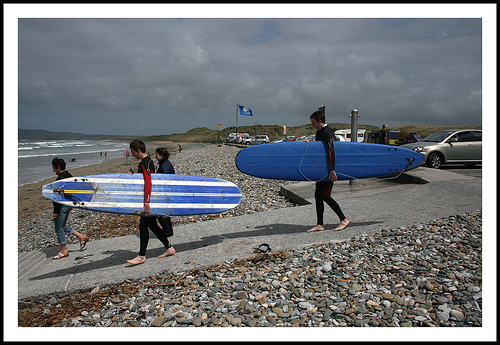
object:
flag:
[238, 104, 253, 117]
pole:
[235, 104, 239, 145]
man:
[306, 109, 350, 233]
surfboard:
[235, 139, 425, 181]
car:
[397, 129, 480, 169]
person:
[50, 157, 88, 260]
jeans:
[53, 205, 76, 244]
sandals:
[52, 253, 69, 260]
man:
[125, 139, 177, 265]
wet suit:
[137, 155, 173, 258]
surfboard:
[39, 172, 246, 217]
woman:
[156, 146, 177, 238]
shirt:
[155, 158, 175, 174]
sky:
[18, 19, 481, 136]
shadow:
[220, 219, 383, 239]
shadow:
[30, 234, 227, 282]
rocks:
[19, 210, 484, 326]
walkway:
[18, 176, 481, 301]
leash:
[297, 140, 416, 184]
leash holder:
[404, 158, 415, 170]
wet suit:
[310, 124, 347, 225]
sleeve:
[141, 165, 153, 203]